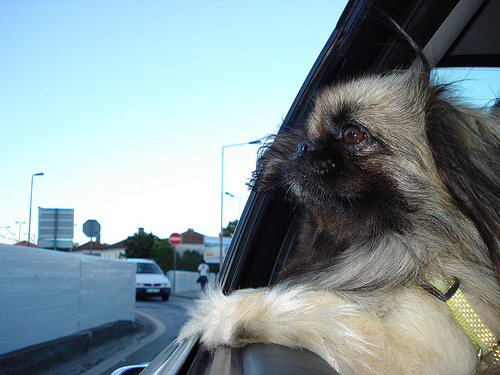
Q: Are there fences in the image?
A: No, there are no fences.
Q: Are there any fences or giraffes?
A: No, there are no fences or giraffes.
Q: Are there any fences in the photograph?
A: No, there are no fences.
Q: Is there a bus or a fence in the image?
A: No, there are no fences or buses.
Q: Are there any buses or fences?
A: No, there are no buses or fences.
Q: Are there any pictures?
A: No, there are no pictures.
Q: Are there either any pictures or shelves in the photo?
A: No, there are no pictures or shelves.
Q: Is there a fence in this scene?
A: No, there are no fences.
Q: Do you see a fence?
A: No, there are no fences.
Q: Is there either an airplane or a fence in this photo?
A: No, there are no fences or airplanes.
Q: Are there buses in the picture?
A: No, there are no buses.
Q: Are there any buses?
A: No, there are no buses.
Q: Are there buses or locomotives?
A: No, there are no buses or locomotives.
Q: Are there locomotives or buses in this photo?
A: No, there are no buses or locomotives.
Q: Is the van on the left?
A: Yes, the van is on the left of the image.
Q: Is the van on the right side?
A: No, the van is on the left of the image.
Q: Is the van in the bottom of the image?
A: Yes, the van is in the bottom of the image.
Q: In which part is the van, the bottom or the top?
A: The van is in the bottom of the image.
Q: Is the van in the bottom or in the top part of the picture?
A: The van is in the bottom of the image.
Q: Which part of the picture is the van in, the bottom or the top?
A: The van is in the bottom of the image.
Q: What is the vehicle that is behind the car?
A: The vehicle is a van.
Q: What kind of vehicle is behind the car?
A: The vehicle is a van.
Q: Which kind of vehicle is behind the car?
A: The vehicle is a van.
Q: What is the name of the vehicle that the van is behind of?
A: The vehicle is a car.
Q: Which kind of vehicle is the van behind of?
A: The van is behind the car.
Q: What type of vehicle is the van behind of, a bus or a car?
A: The van is behind a car.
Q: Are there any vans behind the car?
A: Yes, there is a van behind the car.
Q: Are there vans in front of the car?
A: No, the van is behind the car.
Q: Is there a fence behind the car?
A: No, there is a van behind the car.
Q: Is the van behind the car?
A: Yes, the van is behind the car.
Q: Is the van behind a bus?
A: No, the van is behind the car.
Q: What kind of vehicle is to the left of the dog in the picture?
A: The vehicle is a van.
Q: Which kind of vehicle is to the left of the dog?
A: The vehicle is a van.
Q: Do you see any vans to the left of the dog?
A: Yes, there is a van to the left of the dog.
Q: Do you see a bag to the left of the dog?
A: No, there is a van to the left of the dog.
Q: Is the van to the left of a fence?
A: No, the van is to the left of the dog.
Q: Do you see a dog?
A: Yes, there is a dog.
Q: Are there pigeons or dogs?
A: Yes, there is a dog.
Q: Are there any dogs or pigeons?
A: Yes, there is a dog.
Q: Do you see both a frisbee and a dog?
A: No, there is a dog but no frisbees.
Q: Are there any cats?
A: No, there are no cats.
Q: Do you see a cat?
A: No, there are no cats.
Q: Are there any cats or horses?
A: No, there are no cats or horses.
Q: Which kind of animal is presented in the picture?
A: The animal is a dog.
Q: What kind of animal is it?
A: The animal is a dog.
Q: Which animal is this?
A: This is a dog.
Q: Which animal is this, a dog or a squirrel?
A: This is a dog.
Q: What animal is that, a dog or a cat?
A: That is a dog.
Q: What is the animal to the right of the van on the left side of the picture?
A: The animal is a dog.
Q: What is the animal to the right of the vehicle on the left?
A: The animal is a dog.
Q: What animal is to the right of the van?
A: The animal is a dog.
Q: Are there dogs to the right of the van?
A: Yes, there is a dog to the right of the van.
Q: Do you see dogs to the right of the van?
A: Yes, there is a dog to the right of the van.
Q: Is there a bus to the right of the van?
A: No, there is a dog to the right of the van.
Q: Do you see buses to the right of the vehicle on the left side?
A: No, there is a dog to the right of the van.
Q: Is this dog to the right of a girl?
A: No, the dog is to the right of the van.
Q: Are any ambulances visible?
A: No, there are no ambulances.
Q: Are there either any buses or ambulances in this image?
A: No, there are no ambulances or buses.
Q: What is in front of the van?
A: The car is in front of the van.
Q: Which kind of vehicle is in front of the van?
A: The vehicle is a car.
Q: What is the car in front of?
A: The car is in front of the van.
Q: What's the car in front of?
A: The car is in front of the van.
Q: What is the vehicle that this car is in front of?
A: The vehicle is a van.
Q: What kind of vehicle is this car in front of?
A: The car is in front of the van.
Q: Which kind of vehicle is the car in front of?
A: The car is in front of the van.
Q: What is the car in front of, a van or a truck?
A: The car is in front of a van.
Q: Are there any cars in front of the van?
A: Yes, there is a car in front of the van.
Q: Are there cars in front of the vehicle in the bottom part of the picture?
A: Yes, there is a car in front of the van.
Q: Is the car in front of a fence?
A: No, the car is in front of the van.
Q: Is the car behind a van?
A: No, the car is in front of a van.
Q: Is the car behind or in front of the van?
A: The car is in front of the van.